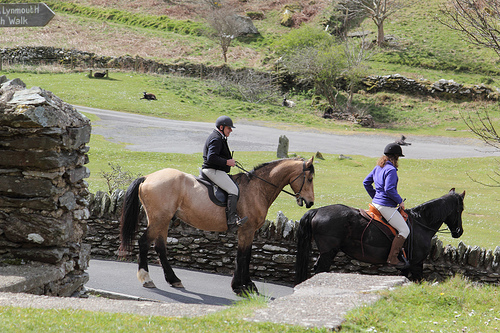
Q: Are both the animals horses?
A: Yes, all the animals are horses.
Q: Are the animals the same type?
A: Yes, all the animals are horses.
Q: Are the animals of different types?
A: No, all the animals are horses.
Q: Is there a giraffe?
A: No, there are no giraffes.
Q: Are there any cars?
A: No, there are no cars.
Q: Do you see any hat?
A: Yes, there is a hat.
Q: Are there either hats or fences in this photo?
A: Yes, there is a hat.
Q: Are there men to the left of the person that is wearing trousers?
A: Yes, there is a man to the left of the person.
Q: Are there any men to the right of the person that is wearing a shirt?
A: No, the man is to the left of the person.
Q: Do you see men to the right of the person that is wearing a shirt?
A: No, the man is to the left of the person.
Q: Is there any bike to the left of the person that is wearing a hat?
A: No, there is a man to the left of the person.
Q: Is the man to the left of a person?
A: Yes, the man is to the left of a person.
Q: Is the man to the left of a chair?
A: No, the man is to the left of a person.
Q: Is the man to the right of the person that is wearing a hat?
A: No, the man is to the left of the person.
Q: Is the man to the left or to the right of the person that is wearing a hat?
A: The man is to the left of the person.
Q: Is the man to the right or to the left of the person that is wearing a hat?
A: The man is to the left of the person.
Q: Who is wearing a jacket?
A: The man is wearing a jacket.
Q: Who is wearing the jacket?
A: The man is wearing a jacket.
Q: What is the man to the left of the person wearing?
A: The man is wearing a jacket.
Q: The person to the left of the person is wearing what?
A: The man is wearing a jacket.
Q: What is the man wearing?
A: The man is wearing a jacket.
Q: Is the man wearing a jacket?
A: Yes, the man is wearing a jacket.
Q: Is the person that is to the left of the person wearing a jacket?
A: Yes, the man is wearing a jacket.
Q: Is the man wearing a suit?
A: No, the man is wearing a jacket.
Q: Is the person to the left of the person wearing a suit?
A: No, the man is wearing a jacket.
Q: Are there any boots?
A: Yes, there are boots.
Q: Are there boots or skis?
A: Yes, there are boots.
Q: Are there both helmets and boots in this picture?
A: Yes, there are both boots and a helmet.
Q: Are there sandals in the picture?
A: No, there are no sandals.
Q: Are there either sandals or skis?
A: No, there are no sandals or skis.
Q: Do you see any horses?
A: Yes, there is a horse.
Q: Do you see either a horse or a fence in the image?
A: Yes, there is a horse.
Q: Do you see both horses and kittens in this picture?
A: No, there is a horse but no kittens.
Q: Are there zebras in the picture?
A: No, there are no zebras.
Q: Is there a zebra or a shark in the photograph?
A: No, there are no zebras or sharks.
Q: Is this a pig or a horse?
A: This is a horse.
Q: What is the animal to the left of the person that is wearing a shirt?
A: The animal is a horse.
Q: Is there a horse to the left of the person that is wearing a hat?
A: Yes, there is a horse to the left of the person.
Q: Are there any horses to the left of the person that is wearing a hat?
A: Yes, there is a horse to the left of the person.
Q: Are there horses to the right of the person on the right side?
A: No, the horse is to the left of the person.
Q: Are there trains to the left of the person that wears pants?
A: No, there is a horse to the left of the person.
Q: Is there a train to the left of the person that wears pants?
A: No, there is a horse to the left of the person.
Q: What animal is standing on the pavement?
A: The horse is standing on the pavement.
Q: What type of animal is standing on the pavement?
A: The animal is a horse.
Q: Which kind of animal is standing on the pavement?
A: The animal is a horse.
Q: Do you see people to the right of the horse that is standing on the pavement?
A: Yes, there is a person to the right of the horse.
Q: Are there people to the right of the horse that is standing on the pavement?
A: Yes, there is a person to the right of the horse.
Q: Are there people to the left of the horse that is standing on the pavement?
A: No, the person is to the right of the horse.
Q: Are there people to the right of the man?
A: Yes, there is a person to the right of the man.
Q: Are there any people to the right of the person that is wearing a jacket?
A: Yes, there is a person to the right of the man.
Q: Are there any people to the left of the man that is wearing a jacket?
A: No, the person is to the right of the man.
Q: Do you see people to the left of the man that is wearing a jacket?
A: No, the person is to the right of the man.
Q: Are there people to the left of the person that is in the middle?
A: No, the person is to the right of the man.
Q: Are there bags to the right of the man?
A: No, there is a person to the right of the man.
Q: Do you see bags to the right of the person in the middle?
A: No, there is a person to the right of the man.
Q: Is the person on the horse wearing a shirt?
A: Yes, the person is wearing a shirt.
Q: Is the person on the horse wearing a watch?
A: No, the person is wearing a shirt.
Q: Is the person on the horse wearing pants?
A: Yes, the person is wearing pants.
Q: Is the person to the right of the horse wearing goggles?
A: No, the person is wearing pants.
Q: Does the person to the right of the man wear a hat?
A: Yes, the person wears a hat.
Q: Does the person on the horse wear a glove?
A: No, the person wears a hat.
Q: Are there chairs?
A: No, there are no chairs.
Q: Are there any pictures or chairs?
A: No, there are no chairs or pictures.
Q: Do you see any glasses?
A: No, there are no glasses.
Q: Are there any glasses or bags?
A: No, there are no glasses or bags.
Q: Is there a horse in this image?
A: Yes, there is a horse.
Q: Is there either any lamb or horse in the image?
A: Yes, there is a horse.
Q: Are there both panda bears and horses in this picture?
A: No, there is a horse but no pandas.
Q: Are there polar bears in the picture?
A: No, there are no polar bears.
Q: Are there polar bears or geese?
A: No, there are no polar bears or geese.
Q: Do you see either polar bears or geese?
A: No, there are no polar bears or geese.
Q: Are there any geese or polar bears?
A: No, there are no polar bears or geese.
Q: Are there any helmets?
A: Yes, there is a helmet.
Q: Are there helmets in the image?
A: Yes, there is a helmet.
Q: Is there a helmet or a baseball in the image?
A: Yes, there is a helmet.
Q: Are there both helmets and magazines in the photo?
A: No, there is a helmet but no magazines.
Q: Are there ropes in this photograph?
A: No, there are no ropes.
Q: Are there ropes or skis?
A: No, there are no ropes or skis.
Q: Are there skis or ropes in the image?
A: No, there are no ropes or skis.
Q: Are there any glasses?
A: No, there are no glasses.